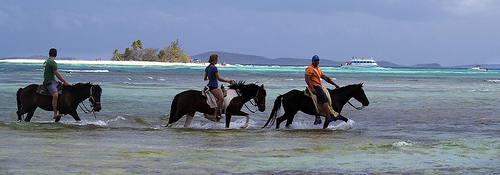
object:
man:
[43, 48, 70, 119]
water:
[84, 131, 155, 164]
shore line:
[0, 61, 211, 67]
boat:
[345, 60, 377, 66]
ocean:
[0, 58, 499, 175]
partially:
[67, 17, 199, 36]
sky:
[0, 0, 499, 68]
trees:
[159, 39, 191, 62]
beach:
[0, 59, 230, 67]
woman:
[203, 54, 231, 119]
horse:
[166, 83, 266, 127]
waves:
[338, 66, 392, 69]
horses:
[273, 84, 369, 129]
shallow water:
[277, 120, 355, 131]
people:
[305, 56, 340, 122]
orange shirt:
[305, 64, 325, 87]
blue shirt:
[205, 66, 218, 87]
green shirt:
[43, 58, 58, 84]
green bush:
[111, 40, 159, 61]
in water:
[275, 128, 343, 134]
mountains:
[191, 51, 273, 64]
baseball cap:
[312, 54, 319, 60]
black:
[286, 95, 308, 109]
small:
[0, 36, 238, 67]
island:
[0, 39, 237, 66]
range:
[159, 39, 190, 62]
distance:
[182, 50, 500, 68]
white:
[234, 118, 257, 129]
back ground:
[0, 0, 499, 67]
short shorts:
[205, 86, 218, 90]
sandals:
[52, 115, 61, 119]